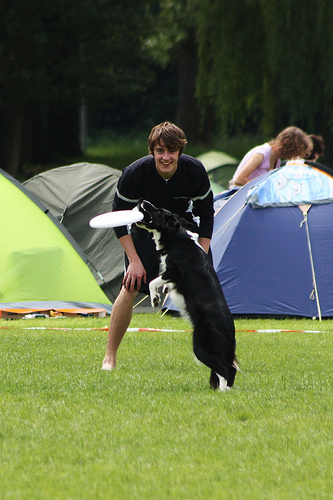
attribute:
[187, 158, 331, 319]
tent — blue, large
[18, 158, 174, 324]
tent — grey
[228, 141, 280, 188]
shirt — sleevelesss, pink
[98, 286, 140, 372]
leg — male, caucasian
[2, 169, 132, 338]
tent — green, little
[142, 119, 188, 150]
hair — cut, brown, short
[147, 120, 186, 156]
hair — brown, short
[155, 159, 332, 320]
tent — blue, little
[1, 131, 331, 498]
grass — short, green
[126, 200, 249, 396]
dog — black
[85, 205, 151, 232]
frisbee — white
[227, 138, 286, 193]
shirt — purple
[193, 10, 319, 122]
leaves — green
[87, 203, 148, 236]
frisbee — white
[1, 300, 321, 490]
field — grassy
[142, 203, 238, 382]
hair — white, black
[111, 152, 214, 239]
shirt — blue